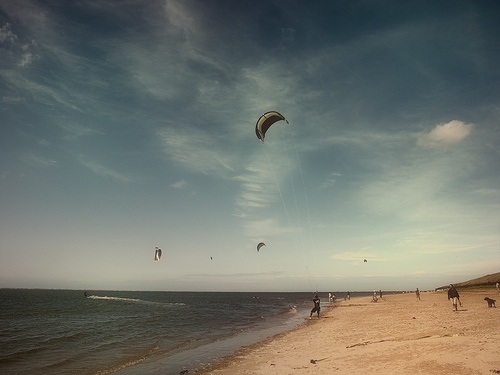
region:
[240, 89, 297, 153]
large parasail in the blue sky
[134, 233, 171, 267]
large parasail in the blue sky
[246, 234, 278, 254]
large parasail in the blue sky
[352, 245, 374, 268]
large parasail in the blue sky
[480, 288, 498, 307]
a black dog on the beach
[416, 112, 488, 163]
a small cloud in the sky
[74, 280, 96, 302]
a person parasailing in the ocean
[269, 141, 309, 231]
white strings on the parasail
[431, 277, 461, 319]
a woman wearing khaki capris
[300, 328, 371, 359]
brown sand on the beach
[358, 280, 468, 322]
People out on beach.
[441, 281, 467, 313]
Woman walking down beach.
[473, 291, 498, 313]
Dog walking on beach.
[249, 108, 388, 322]
People flying kites on beach.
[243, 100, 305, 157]
Huge blue and white kite in sky.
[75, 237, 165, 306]
Man out on water kitesurfing.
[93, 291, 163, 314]
Waves in water left by man kitesurfing.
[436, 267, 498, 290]
Slop of hill extending onto beach.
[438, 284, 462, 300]
Woman dressed in dark color jacket.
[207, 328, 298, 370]
Shoreline of beach and water.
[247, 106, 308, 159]
kite flying in the sky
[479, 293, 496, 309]
dog on the beach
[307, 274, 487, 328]
people on the beach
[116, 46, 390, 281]
several kites in the sky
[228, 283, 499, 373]
shore is coverd in sand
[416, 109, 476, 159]
thick white cloud in the sky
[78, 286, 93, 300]
person in the water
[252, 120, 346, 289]
white strings hanging down from the kite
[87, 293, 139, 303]
wake in the water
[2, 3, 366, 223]
thin white clouds in the sky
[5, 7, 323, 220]
thin white clouds in sky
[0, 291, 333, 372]
surface of blue water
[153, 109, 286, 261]
parasails floating in sky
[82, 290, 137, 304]
person on water surface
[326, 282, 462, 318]
people on sandy beach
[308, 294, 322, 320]
person holding cords of parasail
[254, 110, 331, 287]
parasail with white cords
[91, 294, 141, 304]
white trail on water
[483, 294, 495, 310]
dog walking on beach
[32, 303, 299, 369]
small waves on water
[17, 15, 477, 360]
day at the beach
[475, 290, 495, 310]
dog standing on the sand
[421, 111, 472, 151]
cloud floating by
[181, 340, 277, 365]
shore line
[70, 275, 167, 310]
rider leaving a wake of water behind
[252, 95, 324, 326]
man on shore pulling on the strings of his kite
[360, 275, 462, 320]
people strolling along the beach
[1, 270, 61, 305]
ocean water meets the sky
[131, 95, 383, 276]
kites fly in the sky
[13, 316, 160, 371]
ripples of water